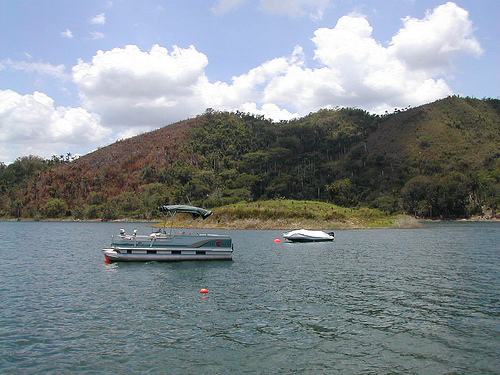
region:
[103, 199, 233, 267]
this is a boat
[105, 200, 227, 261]
the boat is floating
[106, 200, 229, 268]
the boat is green in color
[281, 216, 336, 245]
this is a floater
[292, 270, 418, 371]
the water is calm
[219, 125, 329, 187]
the trees are in a place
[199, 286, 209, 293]
the floater is pink in color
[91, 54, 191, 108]
the cloud is white in color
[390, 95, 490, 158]
this is a hill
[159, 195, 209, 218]
this is a shade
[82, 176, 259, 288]
boat setting in water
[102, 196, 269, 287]
pontoon boat in water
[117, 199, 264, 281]
canopy over the boat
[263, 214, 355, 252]
covering over boat in water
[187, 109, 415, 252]
hills along the water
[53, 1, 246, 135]
white clouds in blue sky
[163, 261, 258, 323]
orange buoy in the water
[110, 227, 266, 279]
blue and white boat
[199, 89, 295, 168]
green trees against clouds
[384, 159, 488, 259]
green trees near water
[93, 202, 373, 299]
Boats in the water.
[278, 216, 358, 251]
The small boat is white.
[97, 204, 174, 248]
People are on the large boat.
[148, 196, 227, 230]
The boat has a green canopy.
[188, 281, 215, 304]
An orange bouy in the water.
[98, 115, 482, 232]
Trees on the hill.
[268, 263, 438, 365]
The water is calm.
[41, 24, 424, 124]
The blue sky is cloudy.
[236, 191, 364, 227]
Grass on top of a hill.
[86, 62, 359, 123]
Clouds in the sky.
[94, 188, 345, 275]
Two boats anchored in water.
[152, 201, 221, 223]
Green canvas top over boat.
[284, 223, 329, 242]
White boat covered over with white canvas.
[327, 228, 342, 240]
Black motor on back of covered boat.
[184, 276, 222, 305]
Orange float in water next to boat.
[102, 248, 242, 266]
Pontoons supporting boat.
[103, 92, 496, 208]
Hills rising on shore.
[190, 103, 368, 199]
Trees growing on side of hills.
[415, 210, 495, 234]
A small cove at edge of water.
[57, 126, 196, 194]
Brown vegetation on slope of hill.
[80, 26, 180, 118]
white clouds in sky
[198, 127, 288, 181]
trees on the island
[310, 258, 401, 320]
water next to island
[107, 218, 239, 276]
ship in the water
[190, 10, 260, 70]
blue sky behind clouds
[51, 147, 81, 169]
tree on top of island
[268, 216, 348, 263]
boat in water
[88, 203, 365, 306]
two boats in the water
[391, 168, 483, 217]
trees on the island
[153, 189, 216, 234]
top part of boat